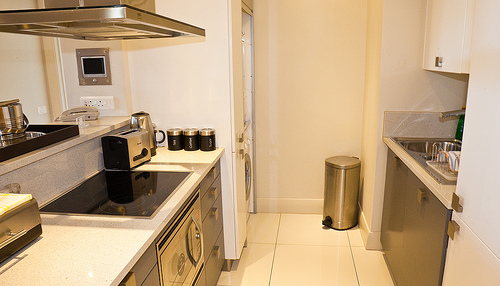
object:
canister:
[166, 128, 183, 151]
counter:
[0, 146, 225, 285]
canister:
[184, 128, 199, 151]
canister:
[198, 128, 217, 152]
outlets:
[83, 98, 94, 109]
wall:
[1, 1, 45, 116]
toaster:
[100, 127, 153, 171]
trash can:
[321, 154, 362, 231]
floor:
[212, 210, 394, 285]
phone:
[55, 105, 101, 122]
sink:
[389, 135, 463, 157]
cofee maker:
[129, 110, 166, 156]